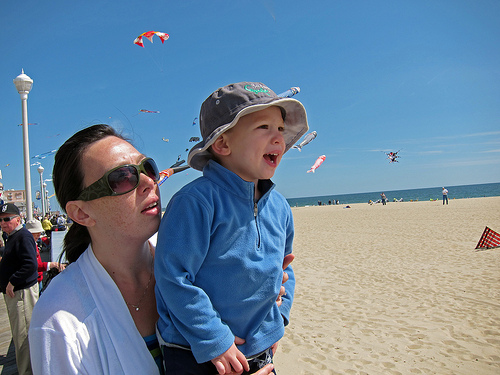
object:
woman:
[25, 111, 164, 375]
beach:
[351, 278, 373, 296]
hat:
[186, 83, 314, 173]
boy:
[153, 75, 308, 374]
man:
[440, 185, 453, 204]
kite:
[130, 25, 174, 53]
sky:
[269, 15, 326, 45]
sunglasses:
[68, 154, 159, 205]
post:
[15, 81, 40, 225]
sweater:
[153, 161, 296, 365]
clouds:
[417, 143, 456, 160]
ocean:
[409, 191, 421, 199]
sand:
[321, 301, 347, 354]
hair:
[78, 132, 87, 141]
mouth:
[259, 149, 286, 168]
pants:
[2, 281, 38, 375]